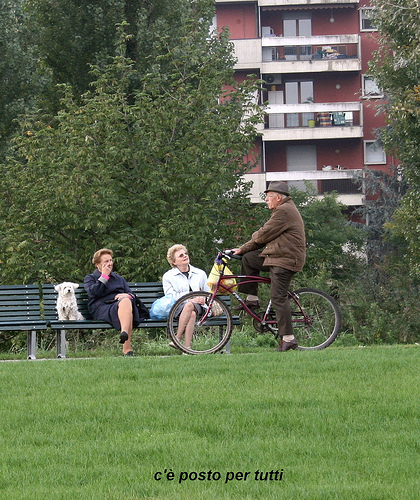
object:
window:
[363, 136, 387, 165]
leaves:
[87, 77, 97, 88]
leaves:
[95, 221, 106, 230]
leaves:
[164, 184, 174, 193]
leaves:
[83, 222, 93, 232]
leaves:
[107, 144, 119, 152]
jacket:
[237, 197, 304, 272]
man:
[231, 179, 307, 351]